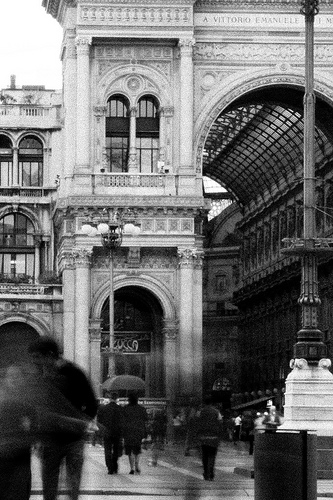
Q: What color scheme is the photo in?
A: Black and white.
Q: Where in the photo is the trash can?
A: On the right.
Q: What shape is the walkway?
A: Arch.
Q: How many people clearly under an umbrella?
A: 2.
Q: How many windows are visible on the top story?
A: 4.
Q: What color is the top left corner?
A: White.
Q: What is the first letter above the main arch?
A: A.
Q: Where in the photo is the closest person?
A: On the left.